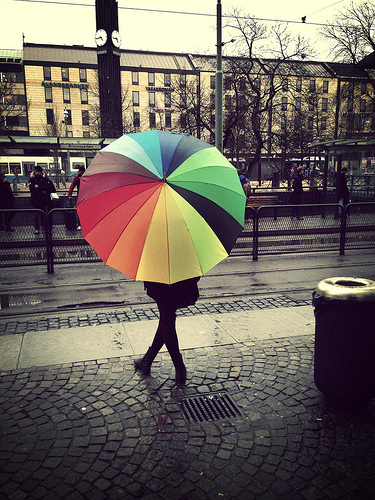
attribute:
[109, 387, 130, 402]
brick — wet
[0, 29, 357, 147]
building — tan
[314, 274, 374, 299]
top — silver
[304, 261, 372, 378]
top — silver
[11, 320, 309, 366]
slab — grey, concrete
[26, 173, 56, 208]
coat — black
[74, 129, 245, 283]
colorful umbrella — open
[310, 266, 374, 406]
trashcan — black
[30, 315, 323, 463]
walkway — cement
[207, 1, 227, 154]
pole — gray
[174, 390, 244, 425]
drain — metal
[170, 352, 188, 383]
boots — black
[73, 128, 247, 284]
umbrella — multi-colroed, multicolored , colorful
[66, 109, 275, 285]
umbrella — large, colorful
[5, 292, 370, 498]
walkway — concrete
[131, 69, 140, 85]
window — black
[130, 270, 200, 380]
woman — holding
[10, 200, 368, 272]
fencing — metal